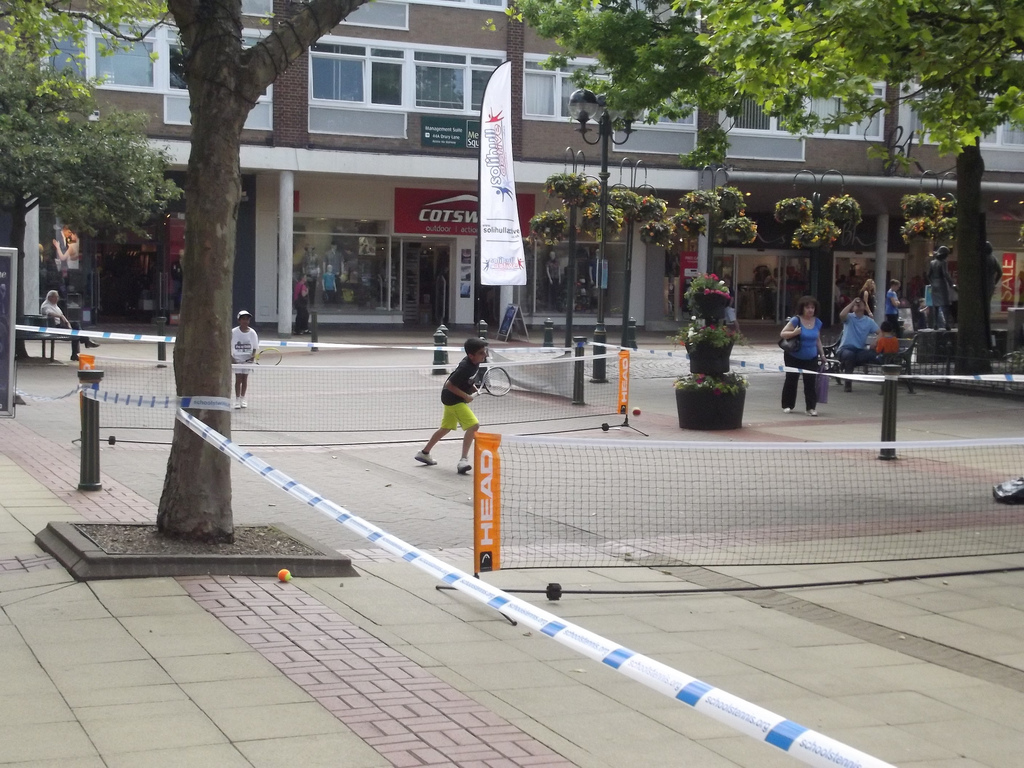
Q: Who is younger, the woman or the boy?
A: The boy is younger than the woman.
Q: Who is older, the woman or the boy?
A: The woman is older than the boy.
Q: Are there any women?
A: Yes, there is a woman.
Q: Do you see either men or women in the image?
A: Yes, there is a woman.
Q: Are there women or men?
A: Yes, there is a woman.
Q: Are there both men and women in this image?
A: Yes, there are both a woman and a man.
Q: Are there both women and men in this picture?
A: Yes, there are both a woman and a man.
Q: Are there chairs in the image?
A: No, there are no chairs.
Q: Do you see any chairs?
A: No, there are no chairs.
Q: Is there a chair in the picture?
A: No, there are no chairs.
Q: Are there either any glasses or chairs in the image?
A: No, there are no chairs or glasses.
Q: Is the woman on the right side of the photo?
A: Yes, the woman is on the right of the image.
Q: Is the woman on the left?
A: No, the woman is on the right of the image.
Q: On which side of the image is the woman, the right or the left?
A: The woman is on the right of the image.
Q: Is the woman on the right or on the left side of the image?
A: The woman is on the right of the image.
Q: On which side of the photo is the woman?
A: The woman is on the right of the image.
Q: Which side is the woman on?
A: The woman is on the right of the image.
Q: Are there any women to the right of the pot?
A: Yes, there is a woman to the right of the pot.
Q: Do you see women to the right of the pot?
A: Yes, there is a woman to the right of the pot.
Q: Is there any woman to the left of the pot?
A: No, the woman is to the right of the pot.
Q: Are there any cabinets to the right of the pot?
A: No, there is a woman to the right of the pot.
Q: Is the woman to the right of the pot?
A: Yes, the woman is to the right of the pot.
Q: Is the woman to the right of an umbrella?
A: No, the woman is to the right of the pot.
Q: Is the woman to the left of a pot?
A: No, the woman is to the right of a pot.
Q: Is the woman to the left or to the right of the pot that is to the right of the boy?
A: The woman is to the right of the pot.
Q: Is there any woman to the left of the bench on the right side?
A: Yes, there is a woman to the left of the bench.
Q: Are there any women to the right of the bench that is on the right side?
A: No, the woman is to the left of the bench.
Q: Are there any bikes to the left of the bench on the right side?
A: No, there is a woman to the left of the bench.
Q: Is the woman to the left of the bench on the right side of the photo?
A: Yes, the woman is to the left of the bench.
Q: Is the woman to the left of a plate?
A: No, the woman is to the left of the bench.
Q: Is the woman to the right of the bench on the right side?
A: No, the woman is to the left of the bench.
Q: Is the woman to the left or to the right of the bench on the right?
A: The woman is to the left of the bench.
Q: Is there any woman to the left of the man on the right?
A: Yes, there is a woman to the left of the man.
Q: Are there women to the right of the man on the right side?
A: No, the woman is to the left of the man.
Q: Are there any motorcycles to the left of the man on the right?
A: No, there is a woman to the left of the man.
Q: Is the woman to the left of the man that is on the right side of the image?
A: Yes, the woman is to the left of the man.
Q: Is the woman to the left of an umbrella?
A: No, the woman is to the left of the man.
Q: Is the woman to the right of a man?
A: No, the woman is to the left of a man.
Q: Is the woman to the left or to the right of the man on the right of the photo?
A: The woman is to the left of the man.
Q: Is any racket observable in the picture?
A: Yes, there is a racket.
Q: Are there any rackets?
A: Yes, there is a racket.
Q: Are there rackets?
A: Yes, there is a racket.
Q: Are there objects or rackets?
A: Yes, there is a racket.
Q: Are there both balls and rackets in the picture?
A: Yes, there are both a racket and balls.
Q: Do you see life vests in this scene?
A: No, there are no life vests.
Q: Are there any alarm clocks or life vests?
A: No, there are no life vests or alarm clocks.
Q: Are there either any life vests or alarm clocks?
A: No, there are no life vests or alarm clocks.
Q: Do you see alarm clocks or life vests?
A: No, there are no life vests or alarm clocks.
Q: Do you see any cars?
A: No, there are no cars.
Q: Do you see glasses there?
A: No, there are no glasses.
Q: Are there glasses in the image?
A: No, there are no glasses.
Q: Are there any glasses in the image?
A: No, there are no glasses.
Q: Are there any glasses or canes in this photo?
A: No, there are no glasses or canes.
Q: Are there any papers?
A: No, there are no papers.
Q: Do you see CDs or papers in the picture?
A: No, there are no papers or cds.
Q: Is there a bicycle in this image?
A: No, there are no bicycles.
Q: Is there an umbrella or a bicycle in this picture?
A: No, there are no bicycles or umbrellas.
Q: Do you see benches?
A: Yes, there is a bench.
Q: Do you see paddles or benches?
A: Yes, there is a bench.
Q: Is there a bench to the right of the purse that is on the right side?
A: Yes, there is a bench to the right of the purse.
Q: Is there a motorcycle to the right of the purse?
A: No, there is a bench to the right of the purse.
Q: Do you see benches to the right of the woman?
A: Yes, there is a bench to the right of the woman.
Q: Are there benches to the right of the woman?
A: Yes, there is a bench to the right of the woman.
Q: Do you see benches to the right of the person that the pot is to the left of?
A: Yes, there is a bench to the right of the woman.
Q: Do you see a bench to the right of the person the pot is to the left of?
A: Yes, there is a bench to the right of the woman.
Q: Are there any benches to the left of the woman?
A: No, the bench is to the right of the woman.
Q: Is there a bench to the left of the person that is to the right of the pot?
A: No, the bench is to the right of the woman.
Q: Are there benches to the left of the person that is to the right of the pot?
A: No, the bench is to the right of the woman.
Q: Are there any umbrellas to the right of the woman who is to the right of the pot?
A: No, there is a bench to the right of the woman.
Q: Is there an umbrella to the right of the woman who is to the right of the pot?
A: No, there is a bench to the right of the woman.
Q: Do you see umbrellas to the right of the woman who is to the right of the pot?
A: No, there is a bench to the right of the woman.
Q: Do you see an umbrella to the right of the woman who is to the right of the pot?
A: No, there is a bench to the right of the woman.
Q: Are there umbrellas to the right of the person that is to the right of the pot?
A: No, there is a bench to the right of the woman.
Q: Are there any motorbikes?
A: No, there are no motorbikes.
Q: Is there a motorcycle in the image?
A: No, there are no motorcycles.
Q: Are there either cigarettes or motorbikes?
A: No, there are no motorbikes or cigarettes.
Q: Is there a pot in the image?
A: Yes, there is a pot.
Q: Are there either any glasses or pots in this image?
A: Yes, there is a pot.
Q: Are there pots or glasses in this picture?
A: Yes, there is a pot.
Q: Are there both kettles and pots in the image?
A: No, there is a pot but no kettles.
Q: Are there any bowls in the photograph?
A: No, there are no bowls.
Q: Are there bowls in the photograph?
A: No, there are no bowls.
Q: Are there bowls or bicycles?
A: No, there are no bowls or bicycles.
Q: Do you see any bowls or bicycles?
A: No, there are no bowls or bicycles.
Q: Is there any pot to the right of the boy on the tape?
A: Yes, there is a pot to the right of the boy.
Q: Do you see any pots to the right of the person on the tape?
A: Yes, there is a pot to the right of the boy.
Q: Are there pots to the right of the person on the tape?
A: Yes, there is a pot to the right of the boy.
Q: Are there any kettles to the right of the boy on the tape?
A: No, there is a pot to the right of the boy.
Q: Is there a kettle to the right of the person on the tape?
A: No, there is a pot to the right of the boy.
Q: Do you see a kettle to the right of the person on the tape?
A: No, there is a pot to the right of the boy.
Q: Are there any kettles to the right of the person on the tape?
A: No, there is a pot to the right of the boy.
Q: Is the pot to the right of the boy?
A: Yes, the pot is to the right of the boy.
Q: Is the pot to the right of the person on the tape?
A: Yes, the pot is to the right of the boy.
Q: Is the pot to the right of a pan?
A: No, the pot is to the right of the boy.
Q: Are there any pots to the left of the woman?
A: Yes, there is a pot to the left of the woman.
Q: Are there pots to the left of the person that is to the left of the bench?
A: Yes, there is a pot to the left of the woman.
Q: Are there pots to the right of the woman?
A: No, the pot is to the left of the woman.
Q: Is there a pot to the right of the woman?
A: No, the pot is to the left of the woman.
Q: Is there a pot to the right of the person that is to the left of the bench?
A: No, the pot is to the left of the woman.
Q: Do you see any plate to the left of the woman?
A: No, there is a pot to the left of the woman.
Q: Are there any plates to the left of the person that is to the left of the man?
A: No, there is a pot to the left of the woman.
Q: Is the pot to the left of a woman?
A: Yes, the pot is to the left of a woman.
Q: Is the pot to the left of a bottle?
A: No, the pot is to the left of a woman.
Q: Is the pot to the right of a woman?
A: No, the pot is to the left of a woman.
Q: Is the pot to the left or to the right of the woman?
A: The pot is to the left of the woman.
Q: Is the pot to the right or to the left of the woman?
A: The pot is to the left of the woman.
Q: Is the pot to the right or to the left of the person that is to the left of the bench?
A: The pot is to the left of the woman.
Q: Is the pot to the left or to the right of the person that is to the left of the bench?
A: The pot is to the left of the woman.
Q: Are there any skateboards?
A: No, there are no skateboards.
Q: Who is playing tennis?
A: The boy is playing tennis.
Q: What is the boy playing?
A: The boy is playing tennis.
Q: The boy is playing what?
A: The boy is playing tennis.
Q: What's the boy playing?
A: The boy is playing tennis.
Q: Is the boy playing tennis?
A: Yes, the boy is playing tennis.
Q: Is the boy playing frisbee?
A: No, the boy is playing tennis.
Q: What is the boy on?
A: The boy is on the tape.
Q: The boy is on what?
A: The boy is on the tape.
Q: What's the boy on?
A: The boy is on the tape.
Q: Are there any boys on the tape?
A: Yes, there is a boy on the tape.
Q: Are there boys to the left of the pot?
A: Yes, there is a boy to the left of the pot.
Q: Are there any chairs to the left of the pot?
A: No, there is a boy to the left of the pot.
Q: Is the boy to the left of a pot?
A: Yes, the boy is to the left of a pot.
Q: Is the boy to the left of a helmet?
A: No, the boy is to the left of a pot.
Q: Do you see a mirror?
A: No, there are no mirrors.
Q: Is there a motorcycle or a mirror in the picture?
A: No, there are no mirrors or motorcycles.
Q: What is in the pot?
A: The plants are in the pot.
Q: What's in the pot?
A: The plants are in the pot.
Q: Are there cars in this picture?
A: No, there are no cars.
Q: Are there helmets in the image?
A: No, there are no helmets.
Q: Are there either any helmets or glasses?
A: No, there are no helmets or glasses.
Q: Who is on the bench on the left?
A: The man is on the bench.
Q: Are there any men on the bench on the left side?
A: Yes, there is a man on the bench.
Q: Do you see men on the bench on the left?
A: Yes, there is a man on the bench.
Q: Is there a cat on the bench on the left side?
A: No, there is a man on the bench.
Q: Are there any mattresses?
A: No, there are no mattresses.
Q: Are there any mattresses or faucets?
A: No, there are no mattresses or faucets.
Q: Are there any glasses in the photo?
A: No, there are no glasses.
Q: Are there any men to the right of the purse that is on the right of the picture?
A: Yes, there is a man to the right of the purse.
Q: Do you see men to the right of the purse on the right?
A: Yes, there is a man to the right of the purse.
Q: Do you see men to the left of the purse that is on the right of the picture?
A: No, the man is to the right of the purse.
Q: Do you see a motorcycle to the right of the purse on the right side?
A: No, there is a man to the right of the purse.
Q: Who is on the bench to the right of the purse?
A: The man is on the bench.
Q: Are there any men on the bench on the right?
A: Yes, there is a man on the bench.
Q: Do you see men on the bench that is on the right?
A: Yes, there is a man on the bench.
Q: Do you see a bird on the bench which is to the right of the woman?
A: No, there is a man on the bench.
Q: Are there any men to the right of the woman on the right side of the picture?
A: Yes, there is a man to the right of the woman.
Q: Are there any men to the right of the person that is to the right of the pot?
A: Yes, there is a man to the right of the woman.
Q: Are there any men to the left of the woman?
A: No, the man is to the right of the woman.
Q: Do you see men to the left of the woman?
A: No, the man is to the right of the woman.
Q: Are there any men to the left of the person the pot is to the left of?
A: No, the man is to the right of the woman.